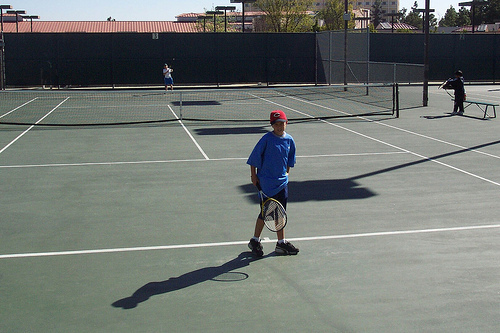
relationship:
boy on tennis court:
[244, 107, 300, 262] [0, 78, 498, 330]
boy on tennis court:
[445, 65, 467, 116] [0, 78, 498, 330]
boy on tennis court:
[160, 59, 177, 96] [0, 78, 498, 330]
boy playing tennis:
[160, 59, 177, 96] [161, 57, 180, 78]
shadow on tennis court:
[168, 94, 232, 107] [0, 78, 498, 330]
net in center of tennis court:
[7, 87, 403, 128] [0, 78, 498, 330]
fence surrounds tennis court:
[316, 28, 429, 114] [0, 78, 498, 330]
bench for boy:
[467, 94, 498, 122] [445, 65, 467, 116]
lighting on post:
[7, 6, 26, 20] [14, 17, 20, 35]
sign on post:
[343, 10, 353, 25] [342, 2, 350, 93]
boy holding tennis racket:
[244, 107, 300, 262] [258, 183, 291, 231]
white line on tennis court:
[176, 111, 217, 164] [0, 78, 498, 330]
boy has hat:
[244, 107, 300, 262] [266, 110, 292, 124]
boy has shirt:
[244, 107, 300, 262] [245, 132, 299, 197]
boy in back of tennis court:
[160, 59, 177, 96] [0, 78, 498, 330]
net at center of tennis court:
[7, 87, 403, 128] [0, 78, 498, 330]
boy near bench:
[445, 65, 467, 116] [467, 94, 498, 122]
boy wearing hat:
[244, 107, 300, 262] [266, 110, 292, 124]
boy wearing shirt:
[244, 107, 300, 262] [245, 132, 299, 197]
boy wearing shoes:
[244, 107, 300, 262] [245, 238, 299, 258]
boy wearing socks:
[244, 107, 300, 262] [250, 236, 291, 243]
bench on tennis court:
[467, 94, 498, 122] [0, 78, 498, 330]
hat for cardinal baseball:
[266, 110, 292, 124] [272, 110, 283, 120]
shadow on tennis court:
[112, 246, 249, 312] [0, 78, 498, 330]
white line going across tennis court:
[176, 111, 217, 164] [0, 78, 498, 330]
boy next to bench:
[445, 65, 467, 116] [467, 94, 498, 122]